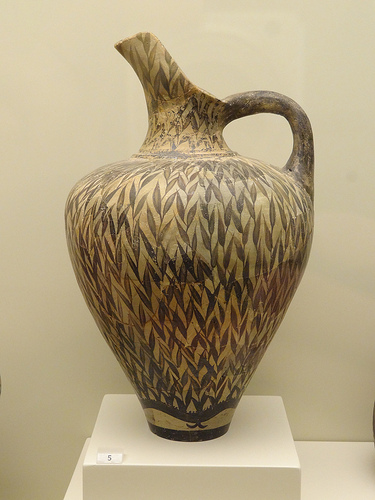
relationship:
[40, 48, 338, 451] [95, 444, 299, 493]
artifact on display stand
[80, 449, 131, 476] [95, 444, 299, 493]
number 5 on display stand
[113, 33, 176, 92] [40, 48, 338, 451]
spout on artifact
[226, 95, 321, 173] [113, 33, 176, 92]
handle near spout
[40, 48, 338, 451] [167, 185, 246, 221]
artifact has brown leaves pattern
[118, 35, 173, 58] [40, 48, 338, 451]
top of artifact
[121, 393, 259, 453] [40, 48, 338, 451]
base of artifact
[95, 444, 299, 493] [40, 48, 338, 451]
display stand for artifact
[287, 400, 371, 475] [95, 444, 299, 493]
area by display stand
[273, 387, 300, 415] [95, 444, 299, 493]
edge of display stand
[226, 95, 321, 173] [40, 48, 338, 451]
handle of artifact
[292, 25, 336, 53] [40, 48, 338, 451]
wall behind artifact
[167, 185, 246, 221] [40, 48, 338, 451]
brown leaves pattern on artifact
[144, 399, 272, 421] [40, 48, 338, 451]
brown trim on artifact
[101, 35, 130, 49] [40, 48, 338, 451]
chip on artifact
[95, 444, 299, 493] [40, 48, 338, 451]
display stand under artifact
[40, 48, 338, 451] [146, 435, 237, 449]
artifact has small base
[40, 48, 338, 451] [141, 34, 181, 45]
artifact has curved lip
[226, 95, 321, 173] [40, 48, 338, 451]
handle on artifact